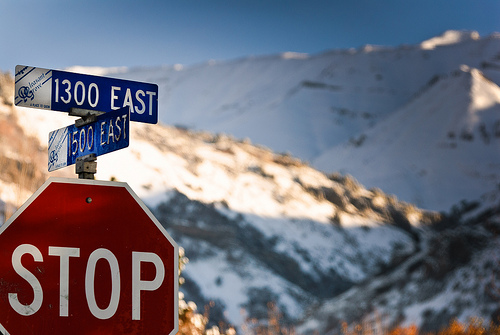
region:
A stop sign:
[2, 171, 169, 333]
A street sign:
[24, 36, 211, 191]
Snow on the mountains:
[258, 65, 423, 187]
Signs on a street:
[43, 48, 188, 306]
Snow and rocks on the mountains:
[248, 137, 300, 224]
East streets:
[50, 113, 174, 219]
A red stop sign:
[30, 201, 173, 318]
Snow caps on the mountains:
[159, 79, 329, 261]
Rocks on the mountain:
[246, 176, 464, 314]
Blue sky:
[119, 25, 186, 34]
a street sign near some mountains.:
[13, 33, 456, 323]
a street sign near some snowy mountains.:
[15, 22, 475, 320]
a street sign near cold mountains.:
[7, 18, 479, 324]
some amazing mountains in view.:
[214, 28, 471, 321]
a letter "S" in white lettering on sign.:
[5, 229, 51, 321]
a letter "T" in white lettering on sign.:
[42, 223, 87, 318]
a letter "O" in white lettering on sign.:
[81, 232, 126, 324]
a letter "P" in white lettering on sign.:
[122, 241, 164, 320]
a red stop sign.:
[5, 178, 180, 333]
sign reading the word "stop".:
[5, 198, 177, 330]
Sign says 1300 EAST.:
[11, 62, 172, 124]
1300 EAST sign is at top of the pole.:
[12, 65, 162, 125]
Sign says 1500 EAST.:
[37, 108, 139, 170]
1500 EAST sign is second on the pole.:
[41, 107, 143, 171]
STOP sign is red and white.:
[0, 178, 188, 333]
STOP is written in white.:
[9, 238, 161, 325]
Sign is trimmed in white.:
[1, 176, 196, 332]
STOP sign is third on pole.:
[0, 176, 186, 332]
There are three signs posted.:
[0, 55, 185, 331]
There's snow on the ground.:
[0, 20, 497, 331]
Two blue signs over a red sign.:
[0, 60, 210, 331]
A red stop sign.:
[0, 170, 185, 330]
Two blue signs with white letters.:
[0, 47, 170, 177]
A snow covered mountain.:
[321, 56, 496, 216]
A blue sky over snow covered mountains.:
[301, 0, 496, 155]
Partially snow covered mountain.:
[181, 175, 326, 285]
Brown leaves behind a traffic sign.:
[92, 230, 243, 332]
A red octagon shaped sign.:
[0, 155, 190, 332]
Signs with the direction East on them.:
[5, 55, 180, 152]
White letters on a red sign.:
[0, 166, 183, 331]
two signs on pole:
[11, 61, 152, 170]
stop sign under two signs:
[1, 174, 181, 333]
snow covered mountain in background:
[202, 58, 419, 135]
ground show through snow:
[247, 228, 299, 275]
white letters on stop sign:
[7, 240, 157, 317]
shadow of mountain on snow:
[245, 209, 350, 256]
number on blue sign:
[50, 76, 105, 110]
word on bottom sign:
[97, 119, 135, 149]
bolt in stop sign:
[79, 192, 96, 210]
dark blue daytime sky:
[382, 2, 452, 28]